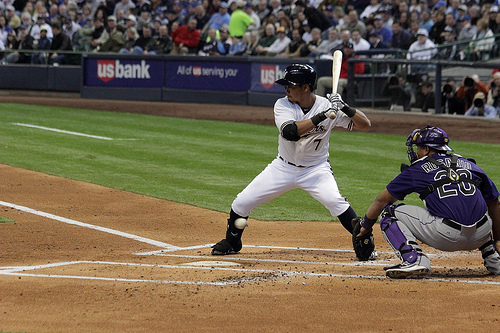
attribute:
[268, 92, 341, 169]
jersey — team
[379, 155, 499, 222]
jersey — team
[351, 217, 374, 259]
mitt — black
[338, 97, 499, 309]
umpire — catcher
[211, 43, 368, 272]
player — baseball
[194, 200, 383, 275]
boots — black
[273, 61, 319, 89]
helmet — shiny, black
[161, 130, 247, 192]
grass — green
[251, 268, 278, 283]
dirt — dark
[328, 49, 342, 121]
bat — wooden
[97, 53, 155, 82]
ad — US Bank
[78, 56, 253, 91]
banner — advertisement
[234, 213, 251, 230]
ball — white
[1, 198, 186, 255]
line — white, chalk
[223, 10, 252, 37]
shirt — Neon green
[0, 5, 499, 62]
crowd — large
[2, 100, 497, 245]
lawn — manicure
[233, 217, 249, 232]
baseball — blurry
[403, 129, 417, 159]
mask — blue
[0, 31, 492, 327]
game — baseball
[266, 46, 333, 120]
hat — hard, black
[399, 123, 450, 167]
helmet — protection